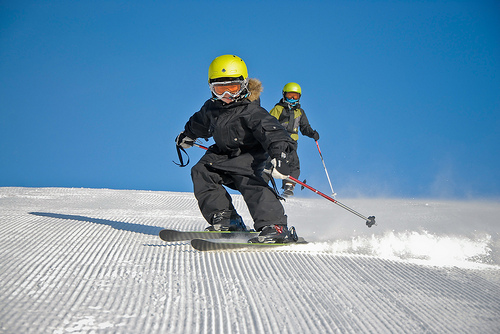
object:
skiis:
[190, 238, 289, 251]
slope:
[1, 186, 496, 331]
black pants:
[191, 143, 287, 232]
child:
[270, 82, 319, 196]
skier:
[270, 67, 315, 194]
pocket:
[262, 125, 288, 140]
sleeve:
[243, 105, 297, 164]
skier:
[160, 50, 295, 256]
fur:
[247, 77, 264, 102]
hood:
[221, 78, 263, 108]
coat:
[183, 78, 298, 184]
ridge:
[0, 236, 77, 308]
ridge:
[158, 247, 174, 333]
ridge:
[140, 246, 156, 332]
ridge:
[210, 254, 230, 333]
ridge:
[260, 240, 310, 334]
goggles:
[284, 92, 301, 100]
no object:
[0, 185, 500, 332]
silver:
[337, 202, 371, 222]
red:
[289, 176, 316, 192]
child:
[174, 55, 297, 244]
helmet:
[208, 54, 248, 84]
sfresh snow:
[272, 227, 497, 268]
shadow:
[26, 212, 165, 235]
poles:
[288, 176, 377, 227]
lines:
[0, 187, 500, 334]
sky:
[0, 1, 500, 198]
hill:
[0, 186, 500, 333]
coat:
[270, 98, 314, 151]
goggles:
[208, 80, 248, 98]